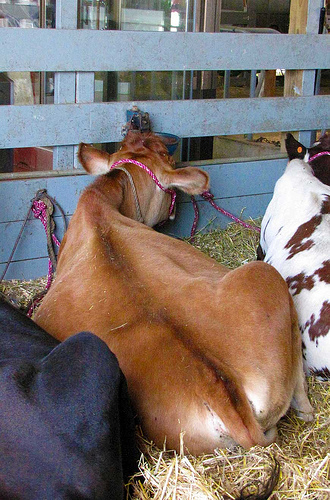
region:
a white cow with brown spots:
[259, 158, 327, 382]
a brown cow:
[33, 132, 310, 446]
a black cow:
[2, 296, 141, 498]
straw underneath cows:
[129, 377, 327, 498]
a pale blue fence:
[3, 5, 328, 190]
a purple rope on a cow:
[110, 153, 220, 241]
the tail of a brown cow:
[195, 362, 282, 458]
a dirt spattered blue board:
[174, 92, 306, 136]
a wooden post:
[278, 2, 320, 149]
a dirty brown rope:
[39, 193, 63, 273]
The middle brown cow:
[31, 122, 314, 454]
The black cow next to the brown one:
[0, 280, 140, 498]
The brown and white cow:
[256, 127, 329, 379]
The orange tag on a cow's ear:
[295, 142, 304, 155]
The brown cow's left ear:
[75, 140, 109, 176]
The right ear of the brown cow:
[162, 161, 211, 199]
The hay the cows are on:
[1, 209, 328, 497]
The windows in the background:
[0, 4, 201, 205]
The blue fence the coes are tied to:
[2, 2, 329, 281]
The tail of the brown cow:
[192, 356, 279, 450]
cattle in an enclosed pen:
[3, 81, 258, 440]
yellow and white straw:
[161, 449, 298, 485]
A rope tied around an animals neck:
[115, 157, 139, 191]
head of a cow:
[90, 142, 216, 198]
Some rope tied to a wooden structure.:
[20, 190, 61, 228]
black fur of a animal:
[12, 340, 62, 406]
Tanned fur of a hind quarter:
[211, 259, 304, 382]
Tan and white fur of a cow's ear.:
[170, 166, 219, 217]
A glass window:
[0, 4, 202, 122]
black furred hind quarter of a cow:
[52, 344, 131, 442]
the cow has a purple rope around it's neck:
[77, 132, 264, 298]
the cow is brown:
[3, 131, 298, 473]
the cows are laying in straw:
[149, 450, 297, 494]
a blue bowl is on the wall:
[121, 106, 189, 158]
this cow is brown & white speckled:
[248, 137, 328, 377]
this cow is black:
[4, 272, 141, 451]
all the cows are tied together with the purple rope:
[23, 147, 328, 323]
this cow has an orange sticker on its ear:
[293, 138, 310, 161]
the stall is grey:
[15, 14, 267, 125]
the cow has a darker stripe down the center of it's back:
[86, 181, 316, 475]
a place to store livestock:
[1, 5, 328, 462]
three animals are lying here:
[6, 3, 328, 482]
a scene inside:
[4, 2, 329, 497]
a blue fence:
[5, 7, 325, 341]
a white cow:
[248, 113, 328, 391]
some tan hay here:
[1, 213, 323, 494]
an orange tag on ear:
[290, 134, 312, 156]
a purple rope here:
[29, 183, 67, 290]